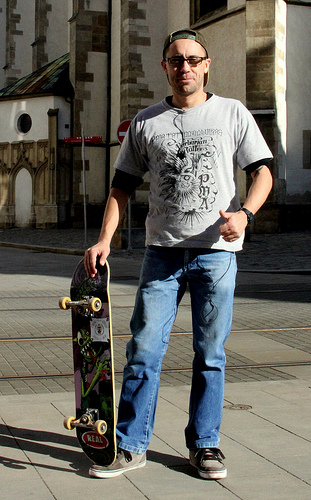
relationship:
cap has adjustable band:
[158, 25, 210, 91] [169, 32, 198, 44]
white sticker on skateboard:
[86, 316, 112, 344] [60, 253, 119, 467]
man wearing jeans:
[81, 27, 276, 480] [107, 241, 238, 455]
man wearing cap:
[81, 27, 276, 480] [158, 25, 210, 91]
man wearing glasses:
[81, 27, 276, 480] [163, 52, 208, 69]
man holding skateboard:
[81, 27, 276, 480] [60, 253, 119, 467]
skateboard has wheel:
[60, 253, 119, 467] [86, 295, 103, 314]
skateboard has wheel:
[60, 253, 119, 467] [63, 412, 80, 433]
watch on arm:
[241, 206, 258, 229] [217, 99, 277, 244]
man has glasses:
[81, 27, 276, 480] [163, 52, 208, 69]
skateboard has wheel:
[60, 253, 119, 467] [91, 418, 110, 436]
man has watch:
[81, 27, 276, 480] [241, 206, 258, 229]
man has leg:
[81, 27, 276, 480] [185, 270, 238, 481]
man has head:
[81, 27, 276, 480] [160, 26, 217, 112]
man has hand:
[81, 27, 276, 480] [216, 203, 255, 250]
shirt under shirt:
[107, 90, 278, 257] [107, 90, 278, 257]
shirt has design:
[107, 90, 278, 257] [152, 137, 220, 231]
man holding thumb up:
[81, 27, 276, 480] [215, 207, 243, 245]